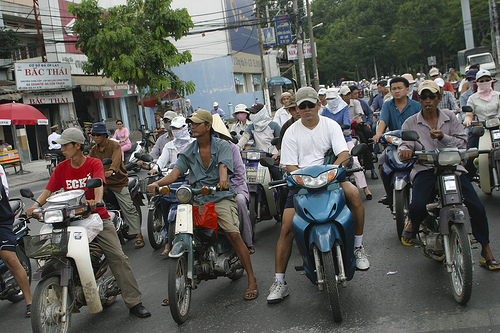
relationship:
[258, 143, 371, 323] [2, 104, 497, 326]
bike in street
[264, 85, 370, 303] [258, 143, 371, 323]
person of bike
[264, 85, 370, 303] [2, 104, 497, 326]
person in street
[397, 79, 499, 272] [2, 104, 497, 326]
person in street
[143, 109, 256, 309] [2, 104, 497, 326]
rider in street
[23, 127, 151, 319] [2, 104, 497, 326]
person in street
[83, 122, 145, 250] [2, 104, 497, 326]
person in street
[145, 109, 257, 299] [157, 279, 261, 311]
rider wearing sandles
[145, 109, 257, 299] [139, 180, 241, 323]
rider of bike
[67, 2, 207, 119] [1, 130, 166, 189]
tree on sidewalk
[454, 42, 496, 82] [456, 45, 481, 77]
truck with back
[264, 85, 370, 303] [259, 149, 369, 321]
person on motorscooter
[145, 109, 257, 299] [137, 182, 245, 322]
rider on motorscooter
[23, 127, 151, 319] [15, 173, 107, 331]
person on motorscooter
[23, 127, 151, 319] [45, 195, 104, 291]
person of scooter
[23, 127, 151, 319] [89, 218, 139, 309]
person wearing pants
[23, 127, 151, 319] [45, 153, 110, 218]
person wearing shirt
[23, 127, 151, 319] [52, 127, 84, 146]
person wearing cap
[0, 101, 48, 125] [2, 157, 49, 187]
umbrella on sidewalk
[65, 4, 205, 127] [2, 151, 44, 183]
tree on sidewalk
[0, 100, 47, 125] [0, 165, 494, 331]
umbrella on sidewalk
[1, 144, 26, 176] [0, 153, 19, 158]
box with stripes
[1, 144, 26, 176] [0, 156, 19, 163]
box with stripe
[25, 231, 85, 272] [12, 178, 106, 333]
basket on front of bike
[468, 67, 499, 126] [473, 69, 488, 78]
person wearing white hat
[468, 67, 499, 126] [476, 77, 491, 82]
person wearing sunglasses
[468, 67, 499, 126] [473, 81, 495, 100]
person wearing pink cloth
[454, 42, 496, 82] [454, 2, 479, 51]
truck in front of pole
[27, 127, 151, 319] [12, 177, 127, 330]
person sitting on bike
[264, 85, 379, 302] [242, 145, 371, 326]
person sitting on bike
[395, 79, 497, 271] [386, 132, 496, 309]
person sitting on bike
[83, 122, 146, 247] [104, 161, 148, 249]
person sitting on bike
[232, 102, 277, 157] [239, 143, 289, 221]
person sitting on bike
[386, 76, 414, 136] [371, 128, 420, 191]
person sitting on bike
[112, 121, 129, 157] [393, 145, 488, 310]
person sitting on bike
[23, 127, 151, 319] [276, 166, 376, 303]
person sitting on motorbike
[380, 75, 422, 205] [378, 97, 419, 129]
man in shirt